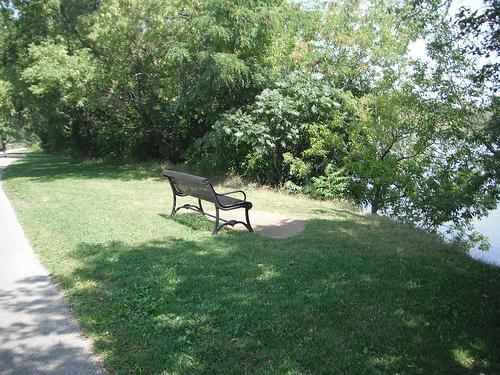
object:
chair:
[161, 168, 255, 234]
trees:
[23, 0, 299, 162]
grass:
[0, 148, 500, 374]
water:
[456, 203, 500, 268]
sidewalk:
[0, 146, 109, 374]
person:
[0, 136, 9, 157]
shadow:
[0, 151, 176, 179]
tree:
[0, 0, 91, 155]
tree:
[406, 150, 499, 236]